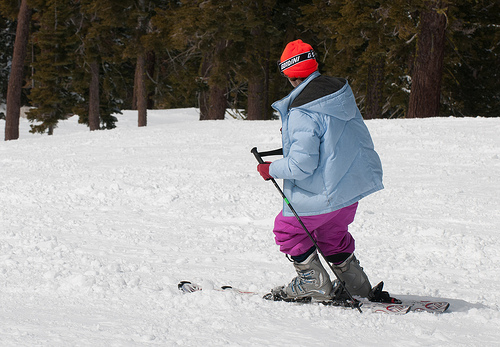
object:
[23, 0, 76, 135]
tree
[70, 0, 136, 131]
tree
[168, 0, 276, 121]
tree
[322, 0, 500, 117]
tree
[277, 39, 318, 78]
beanie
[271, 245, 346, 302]
boot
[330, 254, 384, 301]
boot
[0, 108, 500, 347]
mountain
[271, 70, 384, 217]
blue coat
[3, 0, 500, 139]
forest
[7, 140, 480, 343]
snow trail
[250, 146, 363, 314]
black pole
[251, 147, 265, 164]
black/pole handle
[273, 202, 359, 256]
knees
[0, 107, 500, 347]
ground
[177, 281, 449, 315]
long skis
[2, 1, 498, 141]
background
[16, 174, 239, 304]
tracks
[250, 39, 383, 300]
person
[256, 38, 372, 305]
clothes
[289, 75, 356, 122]
hood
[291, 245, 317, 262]
socks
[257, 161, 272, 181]
glove